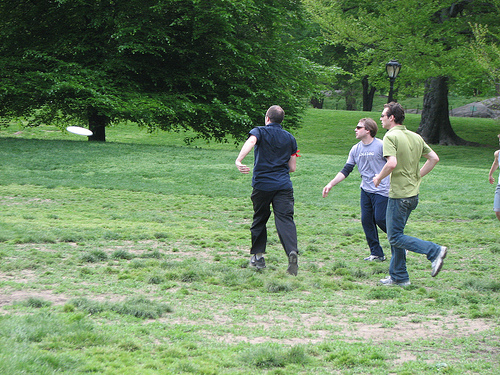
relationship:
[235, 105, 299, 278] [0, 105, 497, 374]
man running in field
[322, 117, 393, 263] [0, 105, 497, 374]
man running in field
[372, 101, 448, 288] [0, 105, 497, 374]
man running in field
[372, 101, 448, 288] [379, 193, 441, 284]
man wearing denim pants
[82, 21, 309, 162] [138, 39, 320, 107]
leaves on tree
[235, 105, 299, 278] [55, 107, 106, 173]
man running toward frisbee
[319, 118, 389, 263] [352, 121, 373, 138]
man wearing sunglasses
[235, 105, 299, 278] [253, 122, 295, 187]
man has back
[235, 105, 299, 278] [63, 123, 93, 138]
man moving toward frisbee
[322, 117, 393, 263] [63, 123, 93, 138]
man moving toward frisbee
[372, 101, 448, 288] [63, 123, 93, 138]
man moving toward frisbee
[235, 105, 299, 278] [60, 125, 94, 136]
man running toward frisbee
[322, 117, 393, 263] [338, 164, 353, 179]
man wearing elbow pad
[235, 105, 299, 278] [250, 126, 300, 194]
man wearing shirt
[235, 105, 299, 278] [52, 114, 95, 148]
man chases frisbee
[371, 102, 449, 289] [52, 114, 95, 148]
man chases frisbee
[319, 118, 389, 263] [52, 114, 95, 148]
man chases frisbee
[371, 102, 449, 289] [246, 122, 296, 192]
man wearing shirt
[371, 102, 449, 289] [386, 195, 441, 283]
man wearing denim pants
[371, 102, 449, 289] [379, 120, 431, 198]
man wearing green shirt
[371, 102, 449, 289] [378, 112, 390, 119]
man wearing sunglasses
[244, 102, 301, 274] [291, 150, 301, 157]
man wearing ribbon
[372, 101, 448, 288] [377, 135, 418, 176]
man has shirt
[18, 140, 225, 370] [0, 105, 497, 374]
grass on field